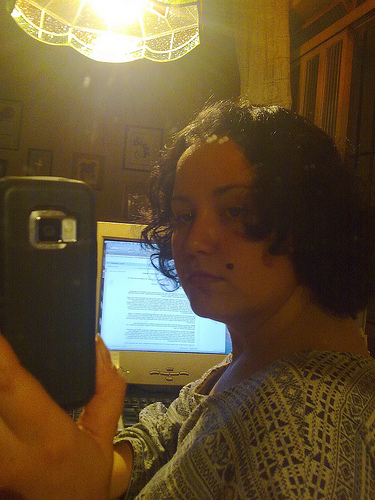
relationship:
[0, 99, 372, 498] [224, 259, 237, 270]
woman has mole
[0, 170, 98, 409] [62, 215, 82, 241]
cellphone has flash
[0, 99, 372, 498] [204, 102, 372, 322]
woman has curly hair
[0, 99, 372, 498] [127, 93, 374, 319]
woman has black hair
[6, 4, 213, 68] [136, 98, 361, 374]
lamp above woman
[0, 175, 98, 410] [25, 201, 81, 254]
cellphone has camera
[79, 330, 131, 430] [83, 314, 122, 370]
thumb has nail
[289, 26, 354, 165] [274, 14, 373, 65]
wooden door on background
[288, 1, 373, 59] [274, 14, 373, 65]
frame on background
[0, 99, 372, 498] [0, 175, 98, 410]
woman holds cellphone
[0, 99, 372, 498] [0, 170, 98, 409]
woman holds cellphone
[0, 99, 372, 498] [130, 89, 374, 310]
woman has curly hair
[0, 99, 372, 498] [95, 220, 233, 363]
woman sitting in front of computer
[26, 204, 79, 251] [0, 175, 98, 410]
camera on cellphone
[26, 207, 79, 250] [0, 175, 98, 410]
flash on cellphone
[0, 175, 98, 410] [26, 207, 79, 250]
cellphone has flash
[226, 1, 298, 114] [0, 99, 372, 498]
curtain behind woman